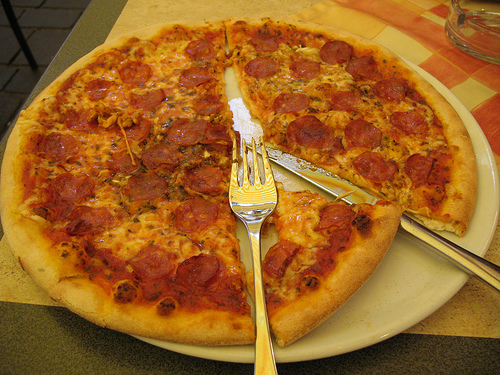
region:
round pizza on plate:
[36, 28, 441, 351]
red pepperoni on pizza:
[170, 253, 219, 293]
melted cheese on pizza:
[134, 213, 194, 267]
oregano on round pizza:
[127, 210, 165, 251]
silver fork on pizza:
[216, 118, 296, 367]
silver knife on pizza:
[282, 156, 482, 261]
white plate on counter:
[111, 24, 473, 314]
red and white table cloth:
[369, 31, 497, 88]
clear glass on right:
[444, 14, 494, 64]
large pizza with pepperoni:
[2, 17, 477, 343]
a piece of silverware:
[229, 140, 283, 373]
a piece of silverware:
[248, 144, 499, 293]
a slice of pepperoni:
[177, 253, 219, 289]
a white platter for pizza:
[128, 54, 498, 364]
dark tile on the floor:
[11, 28, 67, 65]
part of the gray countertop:
[0, 3, 136, 167]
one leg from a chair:
[0, 0, 37, 72]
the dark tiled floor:
[1, 0, 93, 142]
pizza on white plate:
[11, 12, 496, 364]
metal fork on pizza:
[213, 129, 298, 373]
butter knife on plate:
[241, 134, 497, 312]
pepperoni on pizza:
[162, 114, 228, 152]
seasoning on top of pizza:
[127, 69, 207, 169]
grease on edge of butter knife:
[267, 145, 354, 187]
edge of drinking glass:
[437, 0, 499, 74]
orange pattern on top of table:
[370, 3, 495, 135]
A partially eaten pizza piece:
[264, 178, 400, 343]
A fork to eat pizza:
[228, 138, 277, 374]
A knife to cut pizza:
[248, 140, 498, 288]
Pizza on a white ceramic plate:
[0, 16, 477, 345]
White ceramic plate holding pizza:
[128, 23, 498, 361]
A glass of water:
[444, 0, 499, 63]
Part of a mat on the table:
[288, 1, 498, 168]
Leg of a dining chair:
[0, 0, 38, 72]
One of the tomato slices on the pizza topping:
[288, 115, 331, 148]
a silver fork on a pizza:
[205, 105, 318, 374]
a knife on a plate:
[236, 102, 498, 304]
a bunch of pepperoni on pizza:
[81, 95, 220, 214]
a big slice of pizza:
[224, 7, 478, 241]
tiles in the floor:
[3, 2, 93, 65]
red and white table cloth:
[371, 4, 498, 108]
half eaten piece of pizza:
[251, 188, 453, 348]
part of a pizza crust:
[266, 294, 366, 348]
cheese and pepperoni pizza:
[92, 85, 209, 209]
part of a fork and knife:
[187, 89, 407, 241]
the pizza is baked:
[90, 52, 295, 205]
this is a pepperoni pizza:
[118, 67, 376, 334]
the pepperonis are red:
[130, 150, 212, 223]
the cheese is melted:
[101, 197, 194, 242]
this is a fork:
[177, 80, 320, 260]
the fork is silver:
[218, 105, 320, 297]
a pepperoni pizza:
[2, 27, 456, 335]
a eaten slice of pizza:
[233, 173, 404, 356]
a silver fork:
[215, 123, 310, 373]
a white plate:
[58, 16, 499, 368]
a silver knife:
[243, 127, 498, 327]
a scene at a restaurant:
[8, 8, 499, 372]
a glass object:
[429, 0, 499, 73]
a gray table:
[8, 4, 493, 365]